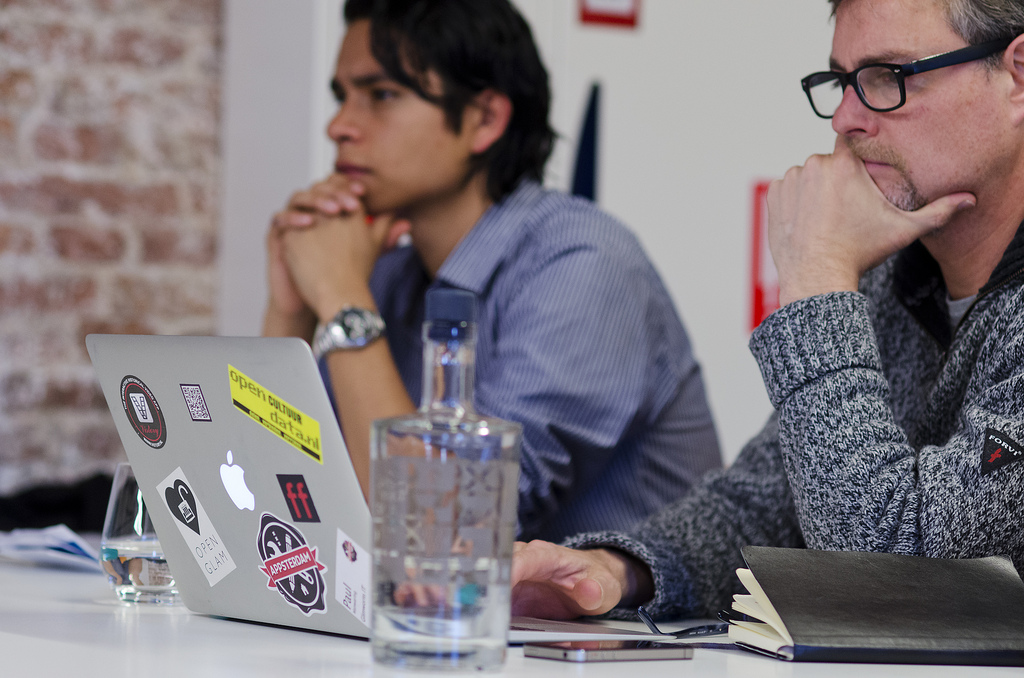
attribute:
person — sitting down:
[510, 0, 1020, 631]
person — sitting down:
[265, 3, 719, 536]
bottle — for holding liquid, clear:
[366, 284, 518, 671]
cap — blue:
[425, 290, 471, 320]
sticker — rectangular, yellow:
[230, 373, 322, 451]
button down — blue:
[319, 179, 727, 538]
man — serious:
[460, 5, 1022, 619]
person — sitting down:
[153, 9, 733, 623]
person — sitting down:
[538, 3, 984, 585]